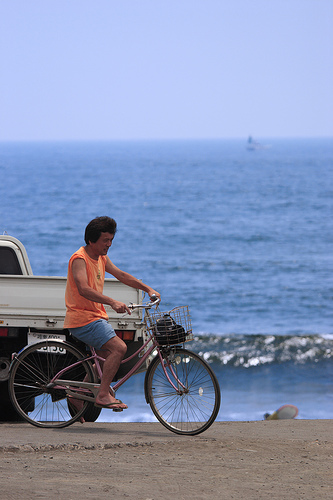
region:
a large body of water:
[1, 132, 331, 421]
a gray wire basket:
[145, 305, 194, 347]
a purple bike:
[7, 294, 222, 434]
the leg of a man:
[66, 317, 127, 396]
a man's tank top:
[64, 240, 112, 328]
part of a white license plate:
[25, 327, 68, 354]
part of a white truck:
[0, 232, 151, 421]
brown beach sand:
[2, 421, 331, 498]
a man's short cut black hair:
[80, 216, 121, 246]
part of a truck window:
[1, 245, 22, 275]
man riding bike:
[32, 198, 204, 435]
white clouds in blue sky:
[14, 4, 56, 48]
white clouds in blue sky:
[165, 98, 192, 120]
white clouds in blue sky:
[226, 65, 250, 101]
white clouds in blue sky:
[65, 65, 108, 103]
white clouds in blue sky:
[141, 70, 183, 109]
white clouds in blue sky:
[162, 36, 215, 95]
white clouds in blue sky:
[242, 39, 331, 122]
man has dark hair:
[82, 209, 124, 251]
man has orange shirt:
[63, 230, 104, 333]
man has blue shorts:
[64, 330, 116, 352]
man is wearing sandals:
[98, 375, 137, 422]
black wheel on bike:
[141, 346, 236, 428]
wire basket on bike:
[153, 308, 183, 344]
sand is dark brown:
[127, 406, 283, 493]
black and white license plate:
[29, 323, 62, 359]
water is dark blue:
[123, 172, 275, 277]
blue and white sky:
[83, 11, 284, 121]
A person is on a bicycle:
[12, 193, 324, 497]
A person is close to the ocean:
[7, 203, 307, 497]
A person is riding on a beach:
[11, 205, 307, 492]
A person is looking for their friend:
[0, 203, 331, 461]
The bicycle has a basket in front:
[3, 207, 309, 471]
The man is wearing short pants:
[5, 207, 292, 466]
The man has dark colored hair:
[47, 206, 159, 260]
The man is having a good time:
[4, 202, 316, 475]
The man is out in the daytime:
[9, 216, 314, 460]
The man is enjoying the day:
[18, 209, 262, 460]